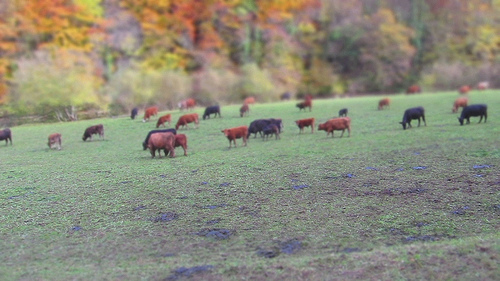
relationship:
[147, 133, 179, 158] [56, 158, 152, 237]
cow eats grass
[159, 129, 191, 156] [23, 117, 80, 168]
cow eats grass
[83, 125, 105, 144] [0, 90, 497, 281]
cow eats field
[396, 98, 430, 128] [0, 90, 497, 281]
cow eats field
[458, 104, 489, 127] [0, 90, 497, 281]
cow eats field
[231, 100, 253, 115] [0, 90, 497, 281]
cow eats field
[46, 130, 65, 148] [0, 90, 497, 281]
cow eats field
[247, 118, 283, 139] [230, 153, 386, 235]
cow eats grass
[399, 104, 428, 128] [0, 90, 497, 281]
cow eats field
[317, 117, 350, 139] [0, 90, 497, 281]
calf eats field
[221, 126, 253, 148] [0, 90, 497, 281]
cow eats field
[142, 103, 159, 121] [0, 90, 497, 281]
cow eats field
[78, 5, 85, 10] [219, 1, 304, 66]
leaf on tree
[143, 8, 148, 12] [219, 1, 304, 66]
leaf on tree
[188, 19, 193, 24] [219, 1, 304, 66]
leaf on tree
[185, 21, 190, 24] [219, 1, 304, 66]
leaf on tree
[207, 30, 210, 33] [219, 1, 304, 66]
leaf on tree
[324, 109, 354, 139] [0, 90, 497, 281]
calf on field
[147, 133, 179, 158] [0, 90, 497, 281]
cow on field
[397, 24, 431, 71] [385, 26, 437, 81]
leaves on tree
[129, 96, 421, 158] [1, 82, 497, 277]
cows on field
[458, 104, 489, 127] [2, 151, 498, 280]
cow on grass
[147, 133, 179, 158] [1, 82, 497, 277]
cow on field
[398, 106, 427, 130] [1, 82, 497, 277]
cow on field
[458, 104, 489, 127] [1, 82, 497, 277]
cow on field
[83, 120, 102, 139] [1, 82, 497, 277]
cow on field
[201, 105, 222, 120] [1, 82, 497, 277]
cow on field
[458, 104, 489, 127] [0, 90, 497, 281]
cow on field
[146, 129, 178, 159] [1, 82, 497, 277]
cow on field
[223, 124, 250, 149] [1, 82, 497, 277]
cow on field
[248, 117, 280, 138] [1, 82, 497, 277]
cow on field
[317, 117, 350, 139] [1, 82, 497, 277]
calf on field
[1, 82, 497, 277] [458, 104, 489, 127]
field on cow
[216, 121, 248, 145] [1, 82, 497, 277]
cows on field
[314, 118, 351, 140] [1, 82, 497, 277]
cows on field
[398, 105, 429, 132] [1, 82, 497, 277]
cows on field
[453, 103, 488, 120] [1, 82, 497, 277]
cows on field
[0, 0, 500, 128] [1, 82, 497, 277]
tree near field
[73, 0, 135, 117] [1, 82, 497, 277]
tree near field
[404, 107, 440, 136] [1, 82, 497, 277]
cows on field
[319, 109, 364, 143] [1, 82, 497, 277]
cows on field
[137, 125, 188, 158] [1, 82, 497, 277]
cows on field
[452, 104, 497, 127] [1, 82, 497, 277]
cows on field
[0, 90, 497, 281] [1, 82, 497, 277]
field on field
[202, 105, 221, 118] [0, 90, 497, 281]
cow on field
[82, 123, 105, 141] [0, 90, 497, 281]
cow on field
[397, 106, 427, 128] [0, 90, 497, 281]
cow on field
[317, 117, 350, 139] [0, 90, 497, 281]
calf on field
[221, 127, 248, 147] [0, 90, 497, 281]
cow on field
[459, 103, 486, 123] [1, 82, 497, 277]
cow on field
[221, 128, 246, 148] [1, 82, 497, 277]
cow on field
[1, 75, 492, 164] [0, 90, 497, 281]
cows on field